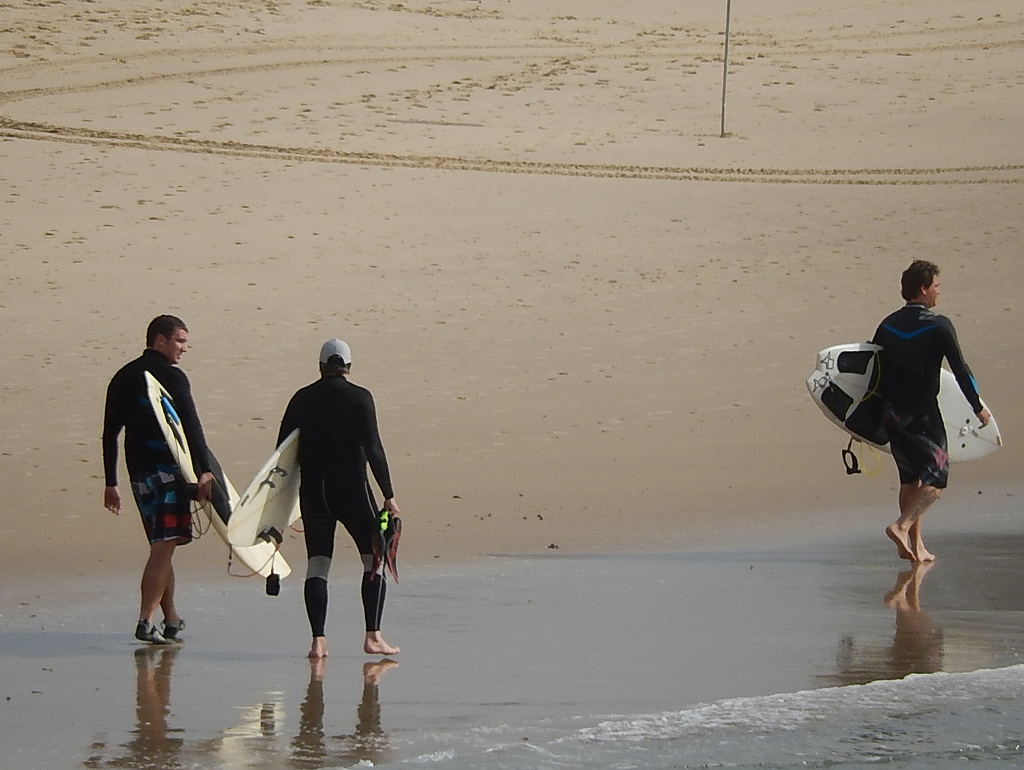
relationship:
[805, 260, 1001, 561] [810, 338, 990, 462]
human holding surfboard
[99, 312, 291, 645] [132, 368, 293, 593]
human carrying surfboard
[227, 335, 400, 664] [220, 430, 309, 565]
human carrying surfboard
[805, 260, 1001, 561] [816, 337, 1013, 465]
human carrying surfboard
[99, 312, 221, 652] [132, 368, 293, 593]
human carrying surfboard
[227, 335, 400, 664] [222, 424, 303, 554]
human carrying surfboard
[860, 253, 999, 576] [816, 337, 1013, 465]
human carrying surfboard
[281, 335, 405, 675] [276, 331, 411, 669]
human carrying surfboard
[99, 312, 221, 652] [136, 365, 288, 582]
human carrying surfboard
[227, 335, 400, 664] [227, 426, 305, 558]
human carrying surfboard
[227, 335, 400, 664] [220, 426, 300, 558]
human carrying surfboard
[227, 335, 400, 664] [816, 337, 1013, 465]
human carrying surfboard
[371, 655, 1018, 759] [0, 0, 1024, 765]
wave washing on shore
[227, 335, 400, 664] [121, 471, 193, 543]
human wearing shorts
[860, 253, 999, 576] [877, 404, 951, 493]
human wearing shorts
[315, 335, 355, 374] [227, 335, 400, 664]
hat on human